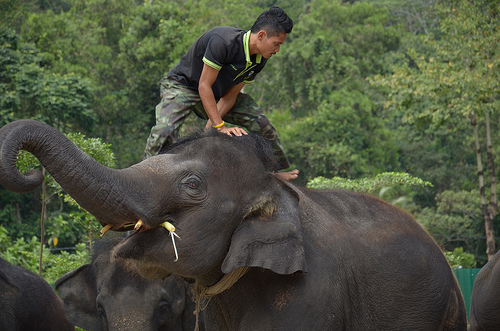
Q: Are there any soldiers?
A: No, there are no soldiers.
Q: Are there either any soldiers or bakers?
A: No, there are no soldiers or bakers.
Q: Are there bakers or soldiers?
A: No, there are no soldiers or bakers.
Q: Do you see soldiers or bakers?
A: No, there are no soldiers or bakers.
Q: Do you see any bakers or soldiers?
A: No, there are no soldiers or bakers.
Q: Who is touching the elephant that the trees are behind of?
A: The man is touching the elephant.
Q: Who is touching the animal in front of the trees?
A: The man is touching the elephant.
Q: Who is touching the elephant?
A: The man is touching the elephant.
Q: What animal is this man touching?
A: The man is touching the elephant.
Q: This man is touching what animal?
A: The man is touching the elephant.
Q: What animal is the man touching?
A: The man is touching the elephant.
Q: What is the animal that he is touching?
A: The animal is an elephant.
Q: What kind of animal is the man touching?
A: The man is touching the elephant.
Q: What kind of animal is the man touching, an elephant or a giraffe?
A: The man is touching an elephant.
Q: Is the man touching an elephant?
A: Yes, the man is touching an elephant.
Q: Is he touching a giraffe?
A: No, the man is touching an elephant.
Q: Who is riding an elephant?
A: The man is riding an elephant.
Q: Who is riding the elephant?
A: The man is riding an elephant.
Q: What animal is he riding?
A: The man is riding an elephant.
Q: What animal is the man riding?
A: The man is riding an elephant.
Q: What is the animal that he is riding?
A: The animal is an elephant.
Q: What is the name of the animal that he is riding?
A: The animal is an elephant.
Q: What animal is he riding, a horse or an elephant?
A: The man is riding an elephant.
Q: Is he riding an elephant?
A: Yes, the man is riding an elephant.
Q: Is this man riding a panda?
A: No, the man is riding an elephant.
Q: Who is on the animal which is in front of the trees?
A: The man is on the elephant.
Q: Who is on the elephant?
A: The man is on the elephant.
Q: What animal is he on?
A: The man is on the elephant.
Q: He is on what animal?
A: The man is on the elephant.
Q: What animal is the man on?
A: The man is on the elephant.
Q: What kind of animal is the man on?
A: The man is on the elephant.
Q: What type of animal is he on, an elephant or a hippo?
A: The man is on an elephant.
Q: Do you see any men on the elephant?
A: Yes, there is a man on the elephant.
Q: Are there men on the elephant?
A: Yes, there is a man on the elephant.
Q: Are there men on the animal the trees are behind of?
A: Yes, there is a man on the elephant.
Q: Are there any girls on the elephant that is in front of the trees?
A: No, there is a man on the elephant.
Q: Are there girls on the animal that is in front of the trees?
A: No, there is a man on the elephant.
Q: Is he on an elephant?
A: Yes, the man is on an elephant.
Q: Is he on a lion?
A: No, the man is on an elephant.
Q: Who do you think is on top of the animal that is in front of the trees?
A: The man is on top of the elephant.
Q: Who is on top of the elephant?
A: The man is on top of the elephant.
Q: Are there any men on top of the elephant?
A: Yes, there is a man on top of the elephant.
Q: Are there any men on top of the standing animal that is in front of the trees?
A: Yes, there is a man on top of the elephant.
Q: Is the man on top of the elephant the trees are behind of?
A: Yes, the man is on top of the elephant.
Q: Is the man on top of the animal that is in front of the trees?
A: Yes, the man is on top of the elephant.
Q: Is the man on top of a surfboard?
A: No, the man is on top of the elephant.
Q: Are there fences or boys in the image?
A: No, there are no fences or boys.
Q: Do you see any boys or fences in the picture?
A: No, there are no fences or boys.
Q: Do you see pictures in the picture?
A: No, there are no pictures.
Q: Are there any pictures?
A: No, there are no pictures.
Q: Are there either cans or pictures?
A: No, there are no pictures or cans.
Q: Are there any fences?
A: No, there are no fences.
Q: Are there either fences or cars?
A: No, there are no fences or cars.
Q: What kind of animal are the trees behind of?
A: The trees are behind the elephant.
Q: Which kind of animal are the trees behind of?
A: The trees are behind the elephant.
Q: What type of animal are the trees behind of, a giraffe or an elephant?
A: The trees are behind an elephant.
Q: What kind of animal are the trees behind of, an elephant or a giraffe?
A: The trees are behind an elephant.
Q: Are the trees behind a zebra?
A: No, the trees are behind an elephant.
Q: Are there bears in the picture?
A: No, there are no bears.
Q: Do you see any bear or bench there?
A: No, there are no bears or benches.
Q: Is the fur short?
A: Yes, the fur is short.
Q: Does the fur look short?
A: Yes, the fur is short.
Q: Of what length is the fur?
A: The fur is short.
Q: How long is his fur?
A: The fur is short.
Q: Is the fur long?
A: No, the fur is short.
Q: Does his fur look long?
A: No, the fur is short.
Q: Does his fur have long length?
A: No, the fur is short.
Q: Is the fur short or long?
A: The fur is short.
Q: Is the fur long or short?
A: The fur is short.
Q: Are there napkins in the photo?
A: No, there are no napkins.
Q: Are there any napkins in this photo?
A: No, there are no napkins.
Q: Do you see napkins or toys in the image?
A: No, there are no napkins or toys.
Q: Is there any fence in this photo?
A: No, there are no fences.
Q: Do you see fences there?
A: No, there are no fences.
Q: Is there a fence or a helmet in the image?
A: No, there are no fences or helmets.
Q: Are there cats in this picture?
A: No, there are no cats.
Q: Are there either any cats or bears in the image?
A: No, there are no cats or bears.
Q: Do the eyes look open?
A: Yes, the eyes are open.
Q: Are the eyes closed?
A: No, the eyes are open.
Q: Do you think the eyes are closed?
A: No, the eyes are open.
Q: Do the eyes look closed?
A: No, the eyes are open.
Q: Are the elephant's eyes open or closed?
A: The eyes are open.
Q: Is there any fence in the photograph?
A: No, there are no fences.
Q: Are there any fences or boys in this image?
A: No, there are no fences or boys.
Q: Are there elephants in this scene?
A: Yes, there is an elephant.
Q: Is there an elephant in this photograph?
A: Yes, there is an elephant.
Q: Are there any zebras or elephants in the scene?
A: Yes, there is an elephant.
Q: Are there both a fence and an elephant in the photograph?
A: No, there is an elephant but no fences.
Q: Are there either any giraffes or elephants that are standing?
A: Yes, the elephant is standing.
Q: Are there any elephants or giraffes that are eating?
A: Yes, the elephant is eating.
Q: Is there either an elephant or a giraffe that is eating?
A: Yes, the elephant is eating.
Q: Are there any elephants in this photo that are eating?
A: Yes, there is an elephant that is eating.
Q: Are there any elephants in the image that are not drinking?
A: Yes, there is an elephant that is eating.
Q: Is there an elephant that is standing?
A: Yes, there is an elephant that is standing.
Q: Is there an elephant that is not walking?
A: Yes, there is an elephant that is standing.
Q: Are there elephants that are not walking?
A: Yes, there is an elephant that is standing.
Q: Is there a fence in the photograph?
A: No, there are no fences.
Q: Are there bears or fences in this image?
A: No, there are no fences or bears.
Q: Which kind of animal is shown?
A: The animal is an elephant.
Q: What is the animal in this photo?
A: The animal is an elephant.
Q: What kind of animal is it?
A: The animal is an elephant.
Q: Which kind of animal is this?
A: This is an elephant.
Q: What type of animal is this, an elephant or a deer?
A: This is an elephant.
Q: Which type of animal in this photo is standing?
A: The animal is an elephant.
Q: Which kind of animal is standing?
A: The animal is an elephant.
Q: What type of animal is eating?
A: The animal is an elephant.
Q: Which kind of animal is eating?
A: The animal is an elephant.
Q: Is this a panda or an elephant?
A: This is an elephant.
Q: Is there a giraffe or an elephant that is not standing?
A: No, there is an elephant but it is standing.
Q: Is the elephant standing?
A: Yes, the elephant is standing.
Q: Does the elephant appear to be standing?
A: Yes, the elephant is standing.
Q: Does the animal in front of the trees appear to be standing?
A: Yes, the elephant is standing.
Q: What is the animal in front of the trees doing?
A: The elephant is standing.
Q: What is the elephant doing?
A: The elephant is standing.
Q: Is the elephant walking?
A: No, the elephant is standing.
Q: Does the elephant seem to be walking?
A: No, the elephant is standing.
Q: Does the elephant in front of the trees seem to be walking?
A: No, the elephant is standing.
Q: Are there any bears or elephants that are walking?
A: No, there is an elephant but it is standing.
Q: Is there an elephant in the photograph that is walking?
A: No, there is an elephant but it is standing.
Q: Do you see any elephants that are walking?
A: No, there is an elephant but it is standing.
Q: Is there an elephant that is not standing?
A: No, there is an elephant but it is standing.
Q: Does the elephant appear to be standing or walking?
A: The elephant is standing.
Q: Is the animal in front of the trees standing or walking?
A: The elephant is standing.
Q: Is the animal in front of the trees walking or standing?
A: The elephant is standing.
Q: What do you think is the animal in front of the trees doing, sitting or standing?
A: The elephant is standing.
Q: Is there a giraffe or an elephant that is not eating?
A: No, there is an elephant but it is eating.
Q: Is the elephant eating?
A: Yes, the elephant is eating.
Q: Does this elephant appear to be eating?
A: Yes, the elephant is eating.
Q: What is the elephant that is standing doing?
A: The elephant is eating.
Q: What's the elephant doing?
A: The elephant is eating.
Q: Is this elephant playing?
A: No, the elephant is eating.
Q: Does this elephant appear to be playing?
A: No, the elephant is eating.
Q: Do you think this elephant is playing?
A: No, the elephant is eating.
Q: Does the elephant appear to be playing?
A: No, the elephant is eating.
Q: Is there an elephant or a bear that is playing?
A: No, there is an elephant but it is eating.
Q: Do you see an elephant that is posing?
A: No, there is an elephant but it is eating.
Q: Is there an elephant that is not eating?
A: No, there is an elephant but it is eating.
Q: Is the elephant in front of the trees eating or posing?
A: The elephant is eating.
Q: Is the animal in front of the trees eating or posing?
A: The elephant is eating.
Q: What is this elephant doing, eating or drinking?
A: The elephant is eating.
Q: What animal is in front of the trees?
A: The elephant is in front of the trees.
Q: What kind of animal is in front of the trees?
A: The animal is an elephant.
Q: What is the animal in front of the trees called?
A: The animal is an elephant.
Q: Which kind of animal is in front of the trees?
A: The animal is an elephant.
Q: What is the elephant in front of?
A: The elephant is in front of the trees.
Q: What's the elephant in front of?
A: The elephant is in front of the trees.